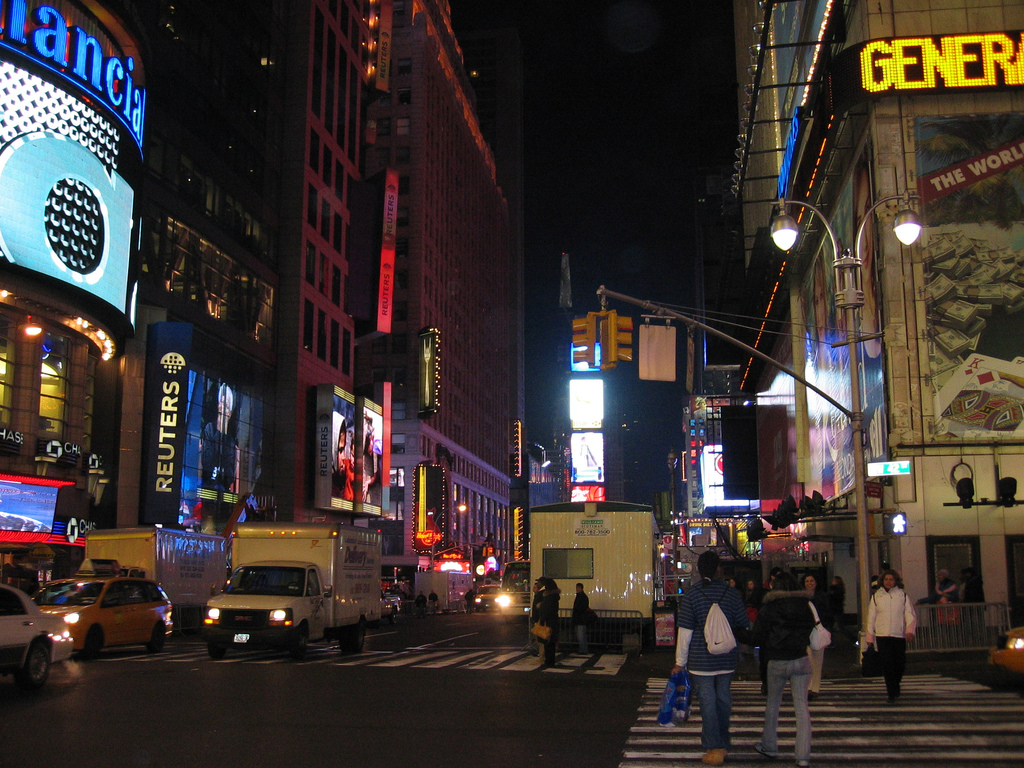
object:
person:
[529, 578, 561, 667]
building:
[2, 0, 293, 601]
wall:
[0, 282, 121, 534]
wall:
[296, 276, 354, 523]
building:
[703, 12, 1024, 641]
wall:
[874, 90, 1024, 652]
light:
[770, 209, 798, 252]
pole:
[832, 249, 871, 665]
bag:
[808, 601, 832, 649]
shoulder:
[758, 604, 815, 661]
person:
[865, 570, 917, 706]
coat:
[865, 586, 915, 642]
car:
[28, 577, 173, 659]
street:
[0, 606, 1024, 768]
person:
[531, 582, 540, 656]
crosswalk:
[69, 639, 658, 682]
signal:
[573, 310, 634, 374]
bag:
[657, 669, 693, 727]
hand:
[673, 665, 687, 676]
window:
[342, 326, 351, 377]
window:
[317, 307, 326, 363]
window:
[329, 318, 340, 371]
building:
[271, 1, 369, 524]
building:
[354, 0, 527, 599]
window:
[332, 263, 341, 308]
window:
[318, 250, 329, 297]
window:
[304, 239, 317, 287]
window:
[307, 180, 318, 230]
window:
[332, 210, 343, 256]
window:
[320, 195, 331, 243]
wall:
[117, 354, 144, 529]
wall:
[167, 304, 279, 569]